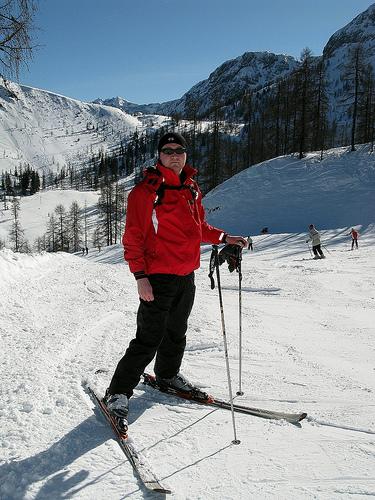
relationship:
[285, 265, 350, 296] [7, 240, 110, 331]
snow in ground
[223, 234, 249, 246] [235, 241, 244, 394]
hand in pole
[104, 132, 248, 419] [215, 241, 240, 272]
man in gloves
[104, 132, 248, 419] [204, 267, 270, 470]
man holds poles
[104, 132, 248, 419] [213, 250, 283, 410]
man holds pole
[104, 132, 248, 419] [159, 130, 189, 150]
man has black cap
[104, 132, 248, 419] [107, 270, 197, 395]
man has pants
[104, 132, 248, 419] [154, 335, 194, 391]
man has boot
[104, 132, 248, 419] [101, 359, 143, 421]
man has boot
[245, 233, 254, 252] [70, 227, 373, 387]
people on hill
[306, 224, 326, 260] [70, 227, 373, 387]
man on hill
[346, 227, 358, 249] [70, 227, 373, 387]
man on hill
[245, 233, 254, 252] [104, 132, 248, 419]
people behind man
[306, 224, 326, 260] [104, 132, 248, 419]
man behind man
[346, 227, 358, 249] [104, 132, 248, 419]
man behind man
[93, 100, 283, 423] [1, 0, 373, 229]
man in mountains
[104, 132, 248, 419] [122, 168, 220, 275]
man wearing jacket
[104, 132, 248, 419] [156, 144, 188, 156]
man wearing sunglasses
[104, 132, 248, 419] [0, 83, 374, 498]
man standing in snow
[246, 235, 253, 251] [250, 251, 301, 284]
people standing in snow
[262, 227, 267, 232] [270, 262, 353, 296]
person standing in snow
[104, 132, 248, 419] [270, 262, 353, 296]
man standing in snow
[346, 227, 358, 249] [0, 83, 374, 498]
man standing in snow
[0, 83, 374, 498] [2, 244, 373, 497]
snow covering ground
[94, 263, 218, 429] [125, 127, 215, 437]
pants on man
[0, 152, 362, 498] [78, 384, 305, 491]
snow on skis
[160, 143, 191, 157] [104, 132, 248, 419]
sunglasses on man